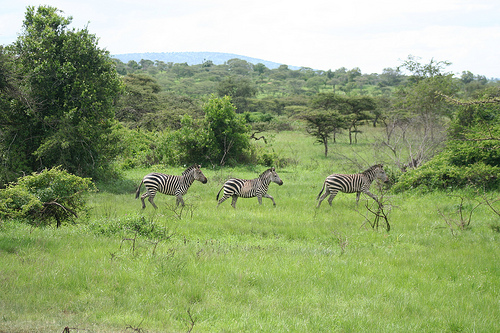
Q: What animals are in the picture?
A: Zebras.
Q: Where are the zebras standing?
A: In grass.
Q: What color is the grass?
A: Green.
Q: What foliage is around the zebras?
A: Trees.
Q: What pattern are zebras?
A: Striped.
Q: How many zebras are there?
A: Three.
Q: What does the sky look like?
A: Clear.